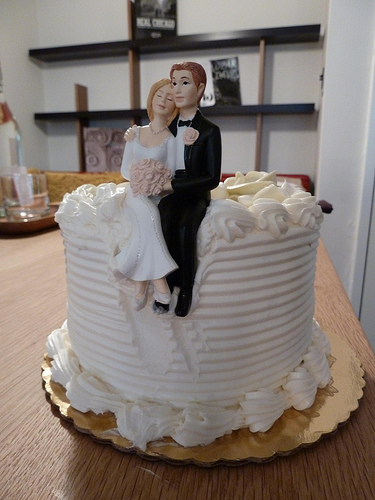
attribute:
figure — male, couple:
[120, 55, 269, 286]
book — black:
[206, 50, 250, 108]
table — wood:
[8, 256, 69, 484]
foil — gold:
[140, 437, 344, 499]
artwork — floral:
[192, 189, 297, 254]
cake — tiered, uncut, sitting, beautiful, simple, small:
[15, 154, 360, 456]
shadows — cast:
[120, 375, 366, 498]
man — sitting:
[170, 62, 235, 242]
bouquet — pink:
[124, 154, 217, 205]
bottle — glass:
[7, 91, 26, 171]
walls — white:
[12, 10, 122, 114]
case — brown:
[52, 21, 143, 112]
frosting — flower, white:
[54, 160, 243, 359]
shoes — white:
[126, 267, 188, 329]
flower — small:
[177, 109, 242, 178]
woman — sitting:
[115, 79, 173, 361]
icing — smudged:
[188, 207, 285, 387]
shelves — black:
[33, 24, 331, 71]